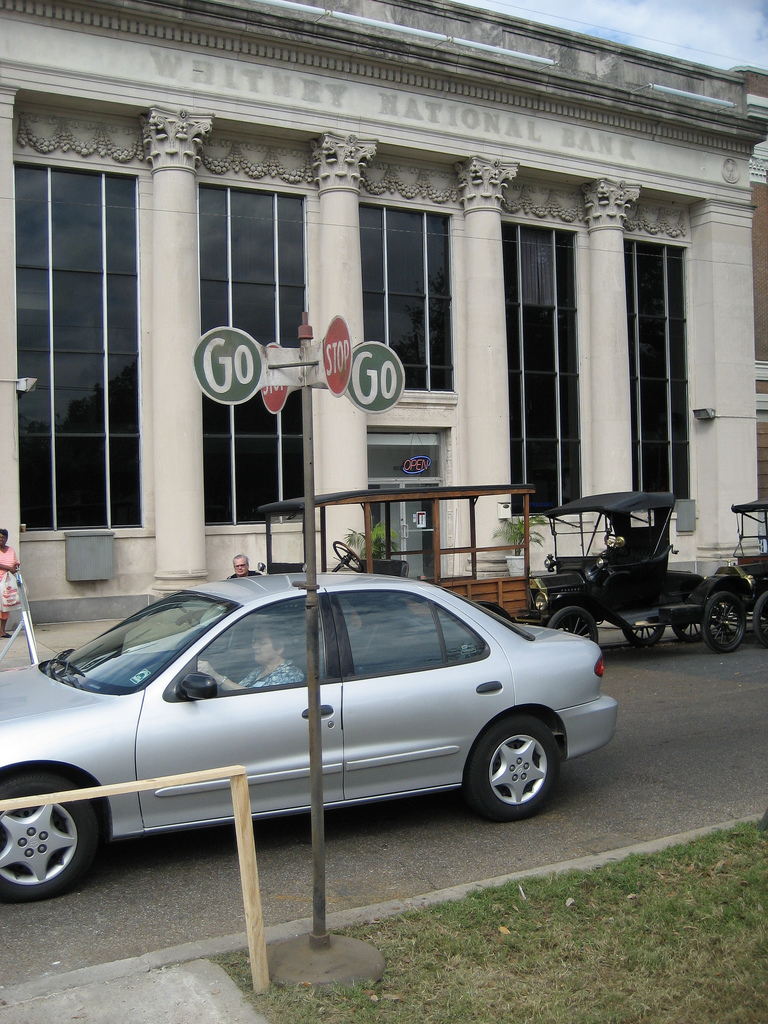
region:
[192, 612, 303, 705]
Driver in the car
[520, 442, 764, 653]
Antique car in front of the building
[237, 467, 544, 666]
Antique wagon in front of the building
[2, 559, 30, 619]
White bag in the hands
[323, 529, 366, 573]
Steering wheel on the wagon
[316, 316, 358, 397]
Red street sign on the pole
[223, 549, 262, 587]
man beside the car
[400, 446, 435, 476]
Neon sign in the window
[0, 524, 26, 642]
Woman in a pink dress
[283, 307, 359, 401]
A stop sign on a post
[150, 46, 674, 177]
Whitney national bank signage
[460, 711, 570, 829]
Rear wheels of a car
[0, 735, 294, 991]
A small wooden fence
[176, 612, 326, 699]
A lady driving a car.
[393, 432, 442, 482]
Open signange behind a pane of glass.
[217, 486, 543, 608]
A man sitting next to an old car.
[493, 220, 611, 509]
Large window panes with white frame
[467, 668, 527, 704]
door handle on a car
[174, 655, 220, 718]
a mirror on a car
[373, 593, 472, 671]
a window in the car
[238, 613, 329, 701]
a woman driving a car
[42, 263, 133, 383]
windows in a building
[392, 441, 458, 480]
a sign in the window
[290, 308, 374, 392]
a sign on a pole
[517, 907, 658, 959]
green grass beside the street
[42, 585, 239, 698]
windshield on gray car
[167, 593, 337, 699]
window on gray car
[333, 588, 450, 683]
window on gray car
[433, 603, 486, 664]
window on gray car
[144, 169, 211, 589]
stone column in front of stone building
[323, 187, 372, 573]
stone column in front of stone building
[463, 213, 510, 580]
stone column in front of stone building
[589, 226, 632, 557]
stone column in front of stone building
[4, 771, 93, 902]
front wheel of gray car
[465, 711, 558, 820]
back wheel of gray car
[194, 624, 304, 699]
woman in a car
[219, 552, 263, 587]
man on the sidewalk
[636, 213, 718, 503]
a window on the building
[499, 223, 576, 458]
a window on the building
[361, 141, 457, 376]
a window on the building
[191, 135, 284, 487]
a window on the building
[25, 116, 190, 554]
a window on the building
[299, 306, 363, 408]
a sign on the pole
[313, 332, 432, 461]
a sign on the pole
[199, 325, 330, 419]
a sign on the pole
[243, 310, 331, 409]
a sign on the pole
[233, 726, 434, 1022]
a tall metal pole